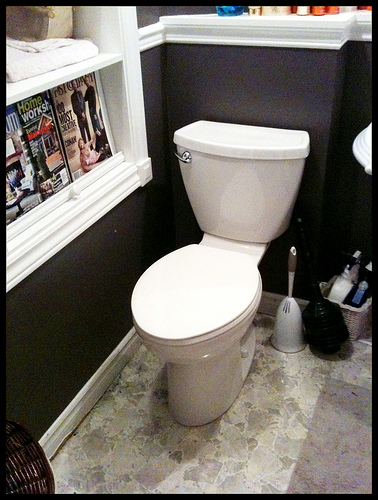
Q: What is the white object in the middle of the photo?
A: Toilet.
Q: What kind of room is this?
A: Bathroom.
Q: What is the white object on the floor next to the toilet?
A: Toilet bowl cleaner.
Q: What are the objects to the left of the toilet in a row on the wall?
A: Magazines.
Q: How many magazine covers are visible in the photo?
A: Three.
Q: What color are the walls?
A: Dark purple.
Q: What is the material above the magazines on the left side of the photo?
A: Towel.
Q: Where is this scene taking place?
A: Bathroom.